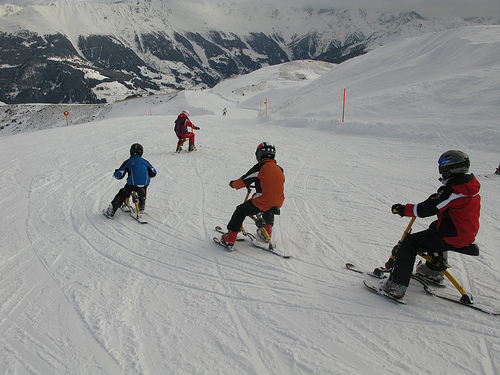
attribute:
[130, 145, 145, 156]
helmet — black, skier's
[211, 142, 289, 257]
person — small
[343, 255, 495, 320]
skis — pair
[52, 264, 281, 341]
snow — white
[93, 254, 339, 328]
marks — ski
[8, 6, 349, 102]
mountain — snow-covered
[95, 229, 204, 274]
tracks — ski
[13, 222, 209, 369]
snow — white